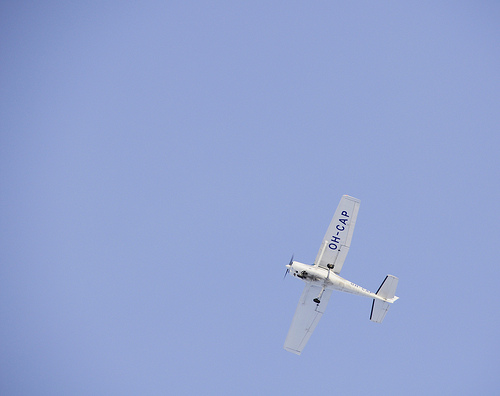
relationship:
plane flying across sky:
[281, 191, 401, 356] [3, 0, 305, 233]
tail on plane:
[364, 270, 402, 324] [257, 190, 425, 352]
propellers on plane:
[275, 250, 295, 275] [281, 191, 401, 356]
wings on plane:
[277, 191, 360, 357] [281, 191, 401, 356]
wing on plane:
[312, 193, 361, 273] [281, 191, 401, 356]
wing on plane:
[278, 277, 333, 357] [281, 191, 401, 356]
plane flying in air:
[281, 191, 401, 356] [3, 5, 498, 391]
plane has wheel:
[281, 191, 401, 356] [328, 263, 334, 268]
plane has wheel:
[281, 191, 401, 356] [313, 297, 320, 303]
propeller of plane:
[280, 251, 300, 281] [281, 191, 401, 356]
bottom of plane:
[271, 184, 417, 360] [281, 193, 401, 356]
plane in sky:
[281, 193, 401, 356] [15, 154, 197, 381]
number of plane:
[324, 208, 349, 251] [272, 190, 404, 348]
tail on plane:
[369, 274, 400, 324] [196, 166, 446, 356]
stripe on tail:
[362, 279, 387, 319] [369, 274, 400, 324]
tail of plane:
[369, 274, 400, 324] [281, 191, 401, 356]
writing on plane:
[324, 211, 349, 252] [266, 170, 446, 357]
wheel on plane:
[312, 297, 319, 303] [281, 191, 401, 356]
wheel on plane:
[326, 263, 334, 268] [281, 191, 401, 356]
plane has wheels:
[281, 193, 401, 356] [321, 260, 335, 270]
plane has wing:
[281, 191, 401, 356] [275, 279, 335, 359]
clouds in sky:
[20, 323, 92, 394] [69, 13, 490, 176]